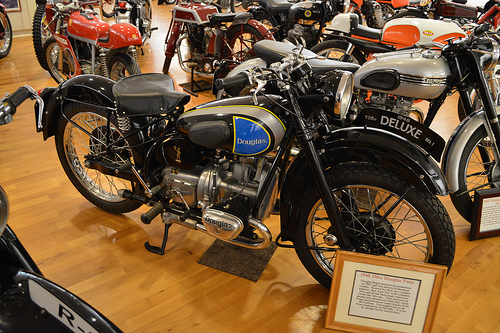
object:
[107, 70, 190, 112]
seat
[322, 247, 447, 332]
frame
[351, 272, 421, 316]
writing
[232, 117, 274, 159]
logo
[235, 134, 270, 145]
douglas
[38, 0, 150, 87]
motorcycle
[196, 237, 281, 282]
rug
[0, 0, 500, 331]
ground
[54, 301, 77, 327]
r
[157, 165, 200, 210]
tank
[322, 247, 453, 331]
photo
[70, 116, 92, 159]
spokes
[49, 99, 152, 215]
wheel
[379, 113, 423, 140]
deluxe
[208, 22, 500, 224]
motorcycle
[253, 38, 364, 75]
seat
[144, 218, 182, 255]
kickstand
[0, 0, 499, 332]
floor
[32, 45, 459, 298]
motorcycles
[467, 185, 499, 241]
certificate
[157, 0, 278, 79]
motorcycle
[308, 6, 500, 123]
motorcycle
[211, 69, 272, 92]
handle bars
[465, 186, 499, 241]
frame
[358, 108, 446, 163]
sign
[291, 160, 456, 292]
wheel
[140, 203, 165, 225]
treads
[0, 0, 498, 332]
display